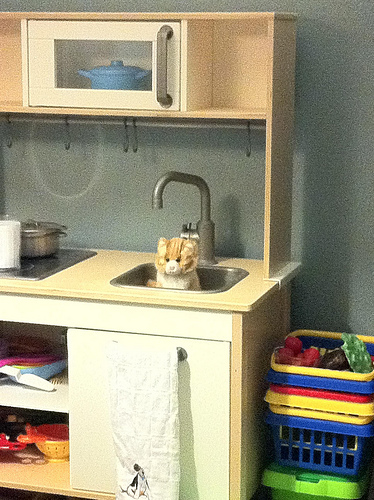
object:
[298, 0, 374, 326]
wall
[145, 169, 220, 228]
faucet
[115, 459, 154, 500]
dog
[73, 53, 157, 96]
bowl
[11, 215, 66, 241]
lid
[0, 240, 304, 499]
counter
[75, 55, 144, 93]
teapot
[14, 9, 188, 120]
microwave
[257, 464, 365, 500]
bin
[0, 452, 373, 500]
bottom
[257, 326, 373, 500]
bins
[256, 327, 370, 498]
stack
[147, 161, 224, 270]
faucet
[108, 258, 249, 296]
sink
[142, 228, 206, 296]
animal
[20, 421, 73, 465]
strainer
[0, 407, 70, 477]
cabinet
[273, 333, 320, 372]
tomatoes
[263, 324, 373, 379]
bin